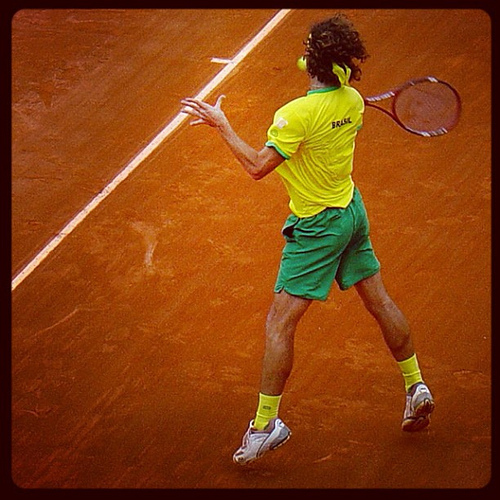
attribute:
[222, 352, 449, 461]
tennis shoes — for tennis , man's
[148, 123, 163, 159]
line — white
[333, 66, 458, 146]
tennis racket — for tennis, swung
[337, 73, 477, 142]
racket — for tennis, man's 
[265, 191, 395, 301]
shorts —   green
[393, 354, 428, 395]
socks — yellow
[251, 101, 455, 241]
shirt — yellow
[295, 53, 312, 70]
ball — Yellow, for tennis, in air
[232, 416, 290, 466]
sneaker — Black and white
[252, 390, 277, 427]
sock — Yellow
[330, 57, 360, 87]
headband — Yellow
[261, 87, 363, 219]
yellow shirt — yellow 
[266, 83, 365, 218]
shirt — yellow, man's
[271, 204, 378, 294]
shorts — man's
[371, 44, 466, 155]
racket — Red and white, for tennis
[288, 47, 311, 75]
ball — tennis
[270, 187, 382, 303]
shorts — green 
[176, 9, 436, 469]
tennis player —  tennis, for tennis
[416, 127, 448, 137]
stripes — White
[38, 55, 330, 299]
court — tennis, clay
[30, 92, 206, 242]
tennis court — for tennis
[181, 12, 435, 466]
player — tennis, gold and green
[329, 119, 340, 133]
letters — black 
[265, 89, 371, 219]
shirt — tennis player's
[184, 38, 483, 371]
player's — tennis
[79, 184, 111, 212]
lines — white